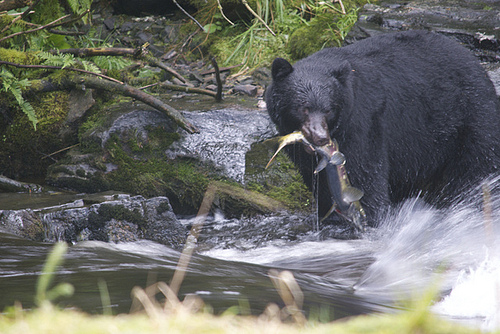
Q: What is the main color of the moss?
A: Green.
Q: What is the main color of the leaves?
A: Green.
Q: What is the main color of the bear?
A: Black.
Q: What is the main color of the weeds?
A: Brown.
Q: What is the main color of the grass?
A: Green.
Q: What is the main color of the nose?
A: Black.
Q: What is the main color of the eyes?
A: Black.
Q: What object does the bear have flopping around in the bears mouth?
A: A fish.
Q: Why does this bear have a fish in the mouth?
A: It's going to eat it.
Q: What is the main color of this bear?
A: Black.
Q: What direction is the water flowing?
A: Right.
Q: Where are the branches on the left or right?
A: Left.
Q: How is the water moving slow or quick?
A: Quick.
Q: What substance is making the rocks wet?
A: Water.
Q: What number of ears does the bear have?
A: 2.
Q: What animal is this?
A: Bear.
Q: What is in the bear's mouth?
A: Fish.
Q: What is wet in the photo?
A: Water.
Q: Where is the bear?
A: In the stream.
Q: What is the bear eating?
A: Fish.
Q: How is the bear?
A: Furry.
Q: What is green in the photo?
A: Trees.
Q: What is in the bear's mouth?
A: Fish.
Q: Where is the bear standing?
A: In a river.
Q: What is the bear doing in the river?
A: Fishing.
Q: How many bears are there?
A: One.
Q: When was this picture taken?
A: Daytime.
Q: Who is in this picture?
A: No one.